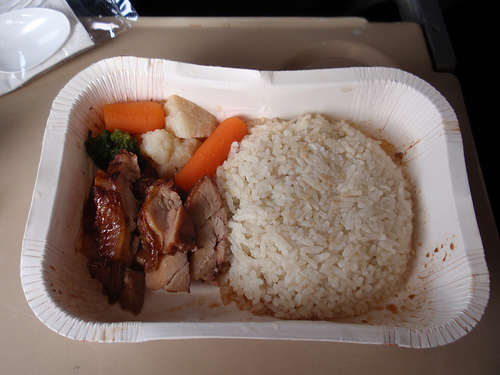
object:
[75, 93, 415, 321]
food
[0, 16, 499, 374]
tray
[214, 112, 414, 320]
rice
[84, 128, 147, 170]
broccoli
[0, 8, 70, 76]
spoon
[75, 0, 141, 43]
wrapper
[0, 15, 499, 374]
table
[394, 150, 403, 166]
sauce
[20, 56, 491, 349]
container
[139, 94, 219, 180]
cauliflower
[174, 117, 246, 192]
carrots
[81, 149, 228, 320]
beef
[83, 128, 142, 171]
veggie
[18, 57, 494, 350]
plate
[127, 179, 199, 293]
pieces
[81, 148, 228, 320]
meat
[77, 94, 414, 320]
meal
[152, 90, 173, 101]
corner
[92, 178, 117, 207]
skin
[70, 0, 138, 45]
plastic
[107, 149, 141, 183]
chicken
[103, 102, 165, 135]
baby carrot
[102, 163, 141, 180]
glaze